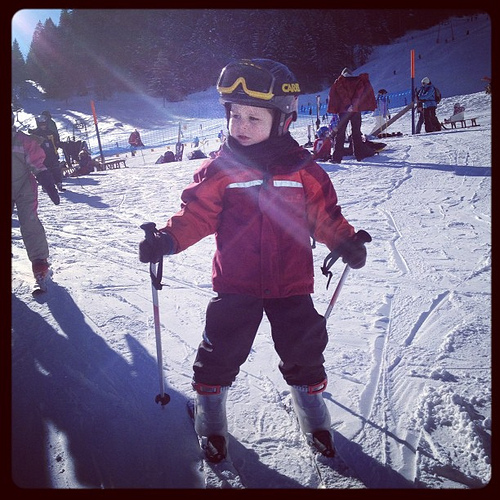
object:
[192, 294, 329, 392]
pants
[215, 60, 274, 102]
eyewear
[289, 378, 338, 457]
boot